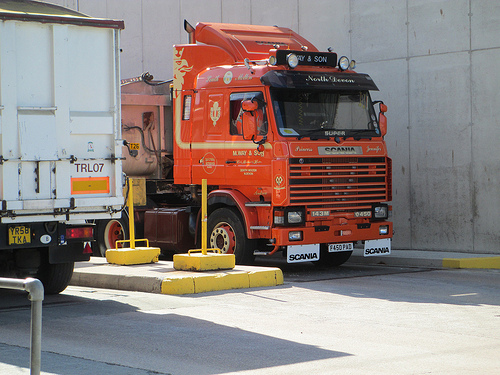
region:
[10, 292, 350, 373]
the shadow of the truck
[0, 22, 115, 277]
the rear view of the truck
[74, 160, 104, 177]
it says TRL07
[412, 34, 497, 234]
a big concrete wall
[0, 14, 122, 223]
this is a white truck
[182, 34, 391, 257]
an orange big truck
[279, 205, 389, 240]
the headlights of the truck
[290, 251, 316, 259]
the word SCANIA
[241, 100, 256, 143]
the rearview mirror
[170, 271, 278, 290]
this area is yellow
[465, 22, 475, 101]
Line in the large concrete wall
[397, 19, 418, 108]
Line in the large concrete wall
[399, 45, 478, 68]
Line in the large concrete wall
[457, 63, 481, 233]
Line in the large concrete wall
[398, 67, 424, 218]
Line in the large concrete wall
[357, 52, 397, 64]
Line in the large concrete wall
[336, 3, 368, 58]
Line in the large concrete wall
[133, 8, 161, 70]
Line in the large concrete wall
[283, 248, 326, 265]
White and black sign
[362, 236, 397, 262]
White and black sign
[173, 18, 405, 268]
Brightly colored cab of truck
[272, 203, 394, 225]
Headlights on front of truck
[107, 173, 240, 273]
Two brightly colored poles in concrete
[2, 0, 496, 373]
Lots of steel and concrete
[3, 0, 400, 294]
Two trucks for hauling heavy loads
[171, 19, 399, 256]
The truck is orange with yellow highlights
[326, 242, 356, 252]
License plate on front of the truck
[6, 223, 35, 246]
License plate on the back of the truck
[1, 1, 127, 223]
The body of the truck is white.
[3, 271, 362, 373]
A shadow of the truck is cast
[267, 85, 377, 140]
the front windshield of a truck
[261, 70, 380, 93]
the black visor on a truck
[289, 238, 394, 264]
two white flaps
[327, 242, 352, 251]
the license plate on a truck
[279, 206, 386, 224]
the front headlights on an orange truck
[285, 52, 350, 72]
flood lights on a truck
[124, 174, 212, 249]
two yellow metal poles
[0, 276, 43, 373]
a gray metal railing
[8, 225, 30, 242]
a yellow license plate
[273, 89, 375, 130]
the windshield on the truck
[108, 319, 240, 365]
a shadow on the ground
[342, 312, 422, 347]
sunlight on the ground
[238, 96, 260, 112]
a mirror on the truck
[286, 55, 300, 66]
clear headlightg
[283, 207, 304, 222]
headlight on the truck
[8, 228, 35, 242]
the license plate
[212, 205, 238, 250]
front tire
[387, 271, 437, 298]
a shadow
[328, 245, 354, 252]
the license plate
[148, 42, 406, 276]
a truck that is red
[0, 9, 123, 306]
a truck that is white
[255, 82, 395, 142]
the windshield of a truck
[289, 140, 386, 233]
the grill of a truck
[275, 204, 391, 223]
the headlights of a truck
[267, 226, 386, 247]
the bumper of a truck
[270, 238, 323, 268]
the mudflap of a truck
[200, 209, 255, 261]
the front wheel of a truck